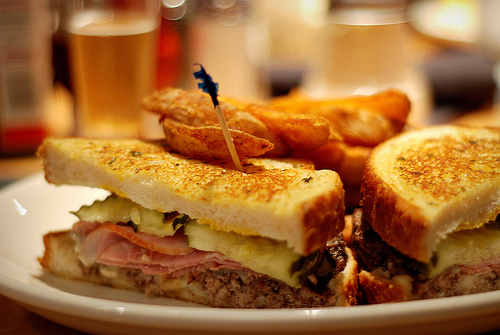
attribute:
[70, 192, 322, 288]
pickles — green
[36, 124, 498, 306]
bread — toasted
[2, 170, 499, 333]
plate — reflective, white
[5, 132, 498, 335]
plate — WHITE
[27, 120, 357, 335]
sandwich — CUT, large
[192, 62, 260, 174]
toothpick — blue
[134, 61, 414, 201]
fries — touching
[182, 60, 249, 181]
toothpick — WOODEN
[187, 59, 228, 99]
plastic — BLUE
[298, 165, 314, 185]
pepper — SMALL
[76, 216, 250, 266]
ham — PINK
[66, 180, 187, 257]
pickle — GREEN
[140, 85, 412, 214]
french fries — golden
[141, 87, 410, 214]
potatoes — fried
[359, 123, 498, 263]
bread — buttered, toasted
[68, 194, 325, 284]
pickle — slices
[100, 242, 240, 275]
ham — sliced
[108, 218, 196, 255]
turkey — sliced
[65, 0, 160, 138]
glass — beer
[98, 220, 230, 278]
meat — pink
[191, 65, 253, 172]
toothpick — small, thin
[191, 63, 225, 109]
plastic — blue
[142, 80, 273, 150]
potatoe — brown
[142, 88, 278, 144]
wedge — seasoned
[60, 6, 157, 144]
cup — large, tall